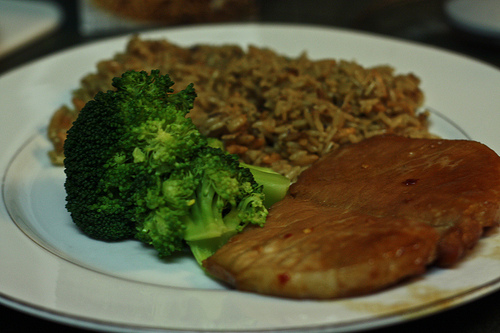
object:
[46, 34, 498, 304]
food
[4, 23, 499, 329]
plate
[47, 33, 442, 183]
rice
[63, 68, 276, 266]
broccoli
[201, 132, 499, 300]
pork chop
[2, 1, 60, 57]
plate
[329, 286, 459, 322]
stain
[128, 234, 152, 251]
shadow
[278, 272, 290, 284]
mark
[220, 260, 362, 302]
edge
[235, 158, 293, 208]
stalk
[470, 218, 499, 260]
sauce